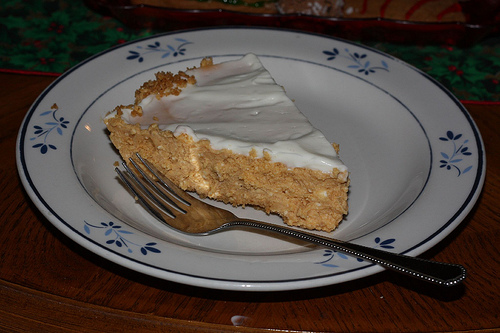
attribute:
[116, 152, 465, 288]
fork — silver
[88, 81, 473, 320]
fork — silver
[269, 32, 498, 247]
plate — white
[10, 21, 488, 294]
saucer — small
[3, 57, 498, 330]
table — dark wood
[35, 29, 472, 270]
flowers — blue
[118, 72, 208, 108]
shell — crumb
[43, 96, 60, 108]
crumb — small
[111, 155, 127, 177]
crumb — small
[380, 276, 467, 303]
shadow — fork